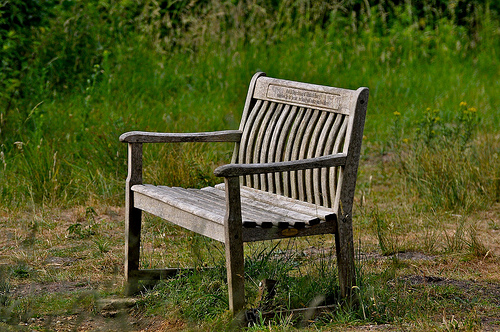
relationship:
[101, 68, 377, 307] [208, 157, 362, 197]
bench has arm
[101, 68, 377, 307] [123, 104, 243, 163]
bench has arm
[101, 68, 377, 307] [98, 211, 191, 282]
bench has leg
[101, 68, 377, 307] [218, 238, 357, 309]
bench has left leg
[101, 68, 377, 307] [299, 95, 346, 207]
bench has left back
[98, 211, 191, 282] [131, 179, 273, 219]
leg has support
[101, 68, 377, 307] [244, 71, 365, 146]
bench has back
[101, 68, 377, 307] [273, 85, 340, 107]
bench has words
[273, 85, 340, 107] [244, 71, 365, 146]
words on back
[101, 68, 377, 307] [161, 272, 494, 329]
bench in weeds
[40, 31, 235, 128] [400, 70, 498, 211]
field has grass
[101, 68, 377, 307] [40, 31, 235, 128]
bench in field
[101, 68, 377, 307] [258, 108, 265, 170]
bench has slats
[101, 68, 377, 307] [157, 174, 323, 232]
bench has seat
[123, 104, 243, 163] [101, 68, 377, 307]
armrest of bench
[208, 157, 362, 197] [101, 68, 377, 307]
armrest of bench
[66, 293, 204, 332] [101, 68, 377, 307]
dirt front of bench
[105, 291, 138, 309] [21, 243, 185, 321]
stone on ground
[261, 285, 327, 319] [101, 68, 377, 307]
stump by bench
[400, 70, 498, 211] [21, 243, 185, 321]
grass on ground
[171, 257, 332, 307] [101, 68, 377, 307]
grass under bench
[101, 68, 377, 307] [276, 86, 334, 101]
bench has words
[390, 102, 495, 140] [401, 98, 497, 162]
flowers on bush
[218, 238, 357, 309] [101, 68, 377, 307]
left leg on bench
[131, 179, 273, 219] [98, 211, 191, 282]
support between leg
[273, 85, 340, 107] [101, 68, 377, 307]
words on bench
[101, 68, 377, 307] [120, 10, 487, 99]
bench by grass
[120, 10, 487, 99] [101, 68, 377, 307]
grass behind bench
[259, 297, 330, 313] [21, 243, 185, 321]
stick on ground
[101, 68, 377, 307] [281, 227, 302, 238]
bench has oval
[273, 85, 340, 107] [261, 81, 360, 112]
words shaped rectangular